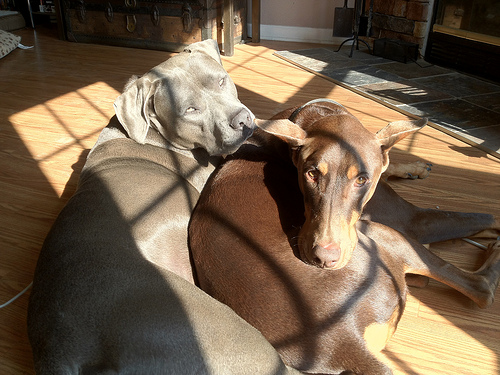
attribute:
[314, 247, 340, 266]
nose — brown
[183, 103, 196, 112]
eye — open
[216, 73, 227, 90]
eye — open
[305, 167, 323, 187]
eye — open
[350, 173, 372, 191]
eye — open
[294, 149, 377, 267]
face — curious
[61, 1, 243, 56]
chest — large, wood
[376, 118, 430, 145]
ear — light brown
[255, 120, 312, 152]
ear — light brown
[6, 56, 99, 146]
floor — hardwood laminate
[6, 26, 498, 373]
floor — wood, brown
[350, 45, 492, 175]
tile — ceramic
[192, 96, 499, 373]
dog — young, short haired, brown, staring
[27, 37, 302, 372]
dog — short haired, grey, staring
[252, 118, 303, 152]
ear — raised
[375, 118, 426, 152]
ear — raised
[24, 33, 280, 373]
bully — brownish , grey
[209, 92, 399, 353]
dog — grey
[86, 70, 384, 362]
dog — dark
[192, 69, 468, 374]
dog — brown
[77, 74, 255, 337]
light — sun